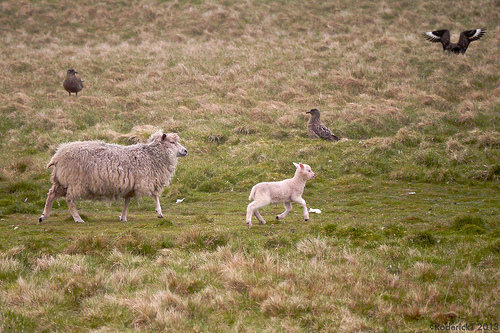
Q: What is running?
A: A lamb.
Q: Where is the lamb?
A: In front of big sheep.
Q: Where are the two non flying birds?
A: Behind the sheep.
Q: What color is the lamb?
A: White.